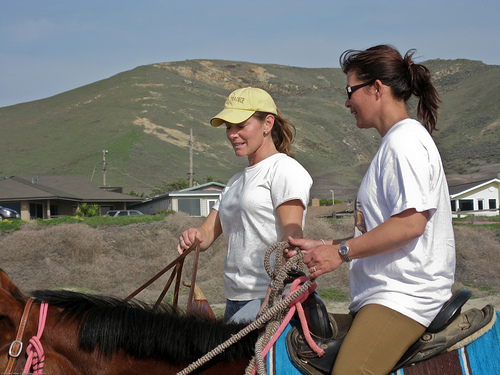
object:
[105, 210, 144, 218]
vehicle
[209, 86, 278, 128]
cap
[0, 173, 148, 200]
roof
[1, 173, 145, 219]
house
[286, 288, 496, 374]
saddle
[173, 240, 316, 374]
rope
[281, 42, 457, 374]
woman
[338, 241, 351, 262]
watch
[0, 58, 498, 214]
mountain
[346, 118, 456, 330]
shirt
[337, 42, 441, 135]
hair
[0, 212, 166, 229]
grass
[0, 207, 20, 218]
vehicle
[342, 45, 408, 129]
head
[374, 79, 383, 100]
ear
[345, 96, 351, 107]
nose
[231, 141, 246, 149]
mouth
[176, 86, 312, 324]
woman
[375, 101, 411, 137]
neck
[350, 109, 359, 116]
lips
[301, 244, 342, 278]
hand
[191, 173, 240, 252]
arm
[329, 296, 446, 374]
leg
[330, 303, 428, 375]
pants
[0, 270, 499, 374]
horse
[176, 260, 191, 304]
halter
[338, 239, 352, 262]
wrist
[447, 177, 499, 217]
home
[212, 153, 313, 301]
shirt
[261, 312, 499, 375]
blanket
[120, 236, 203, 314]
rein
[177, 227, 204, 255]
hand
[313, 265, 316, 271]
ring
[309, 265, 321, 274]
finger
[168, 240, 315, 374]
rein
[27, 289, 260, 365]
mane